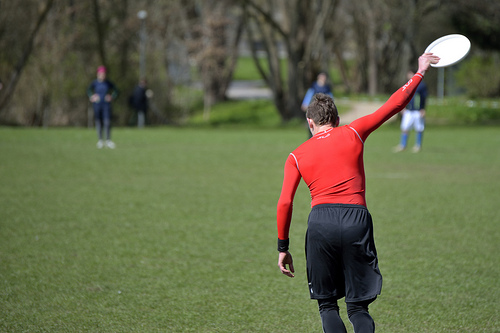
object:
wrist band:
[277, 238, 289, 251]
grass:
[446, 284, 497, 331]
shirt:
[276, 74, 423, 239]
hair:
[306, 93, 339, 131]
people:
[394, 67, 427, 156]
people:
[88, 65, 121, 150]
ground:
[381, 220, 436, 266]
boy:
[277, 32, 471, 330]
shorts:
[303, 203, 382, 302]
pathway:
[336, 90, 401, 126]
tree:
[367, 9, 414, 93]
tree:
[243, 0, 330, 122]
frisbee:
[424, 32, 472, 67]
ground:
[386, 159, 482, 195]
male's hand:
[416, 52, 440, 75]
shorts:
[303, 203, 385, 307]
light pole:
[136, 10, 153, 130]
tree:
[63, 0, 109, 65]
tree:
[111, 0, 152, 79]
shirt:
[86, 78, 119, 104]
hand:
[277, 253, 295, 280]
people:
[130, 67, 151, 138]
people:
[302, 71, 332, 139]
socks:
[347, 299, 376, 333]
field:
[57, 149, 257, 315]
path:
[228, 84, 267, 99]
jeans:
[94, 105, 114, 139]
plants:
[422, 92, 485, 131]